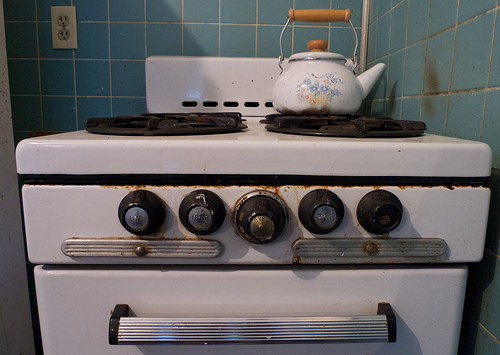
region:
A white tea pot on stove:
[261, 5, 394, 121]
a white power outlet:
[40, 5, 87, 55]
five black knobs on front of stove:
[111, 177, 461, 267]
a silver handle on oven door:
[86, 295, 427, 350]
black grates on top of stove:
[82, 75, 412, 150]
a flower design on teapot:
[282, 57, 352, 107]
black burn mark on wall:
[405, 47, 460, 118]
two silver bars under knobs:
[41, 235, 466, 265]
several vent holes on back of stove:
[166, 90, 306, 115]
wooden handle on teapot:
[285, 10, 355, 28]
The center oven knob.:
[225, 192, 290, 257]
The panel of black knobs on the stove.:
[110, 188, 430, 240]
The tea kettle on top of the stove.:
[262, 9, 387, 116]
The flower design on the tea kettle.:
[296, 66, 347, 116]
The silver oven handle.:
[101, 295, 426, 354]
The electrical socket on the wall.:
[47, 7, 83, 53]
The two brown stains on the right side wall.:
[407, 43, 442, 120]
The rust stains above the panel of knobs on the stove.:
[99, 186, 446, 206]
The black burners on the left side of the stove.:
[87, 101, 247, 138]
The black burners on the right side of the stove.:
[261, 97, 428, 149]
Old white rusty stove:
[11, 4, 491, 349]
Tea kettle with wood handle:
[255, 2, 402, 124]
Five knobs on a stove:
[78, 163, 421, 240]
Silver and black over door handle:
[90, 292, 416, 350]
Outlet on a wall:
[37, 1, 90, 62]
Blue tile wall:
[91, 0, 262, 48]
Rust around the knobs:
[30, 155, 484, 204]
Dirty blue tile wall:
[386, 10, 490, 131]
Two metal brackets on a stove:
[29, 206, 471, 287]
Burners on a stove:
[79, 105, 446, 146]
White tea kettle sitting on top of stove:
[267, 3, 388, 118]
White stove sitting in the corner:
[10, 48, 496, 351]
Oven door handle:
[97, 297, 397, 352]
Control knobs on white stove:
[100, 180, 412, 245]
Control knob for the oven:
[225, 182, 298, 254]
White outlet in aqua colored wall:
[43, 2, 79, 47]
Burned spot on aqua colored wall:
[407, 40, 452, 125]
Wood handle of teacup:
[278, 3, 353, 26]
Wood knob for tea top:
[303, 33, 330, 51]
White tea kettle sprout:
[353, 58, 387, 94]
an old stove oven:
[7, 0, 486, 352]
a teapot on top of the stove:
[264, 3, 422, 138]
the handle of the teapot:
[270, 2, 363, 42]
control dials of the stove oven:
[111, 179, 411, 249]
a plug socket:
[46, 2, 81, 58]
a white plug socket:
[43, 2, 82, 54]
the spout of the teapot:
[360, 55, 388, 90]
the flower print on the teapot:
[287, 68, 350, 104]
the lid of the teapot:
[286, 37, 350, 62]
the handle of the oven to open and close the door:
[98, 302, 403, 352]